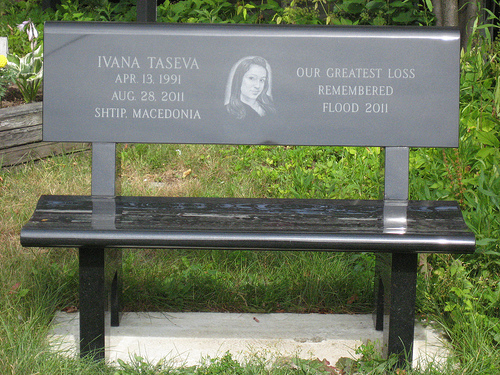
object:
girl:
[220, 52, 278, 128]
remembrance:
[88, 45, 417, 133]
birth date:
[112, 68, 186, 86]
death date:
[107, 88, 187, 105]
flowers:
[0, 43, 42, 107]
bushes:
[90, 0, 135, 24]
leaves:
[473, 122, 500, 150]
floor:
[38, 303, 466, 375]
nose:
[253, 81, 261, 90]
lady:
[222, 50, 281, 127]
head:
[236, 53, 273, 102]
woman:
[218, 54, 275, 119]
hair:
[227, 53, 278, 120]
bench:
[12, 11, 486, 366]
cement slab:
[29, 298, 469, 373]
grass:
[2, 47, 495, 373]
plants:
[0, 2, 42, 24]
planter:
[0, 83, 106, 168]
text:
[287, 51, 425, 132]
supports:
[71, 243, 434, 371]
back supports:
[380, 141, 416, 201]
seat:
[13, 185, 483, 255]